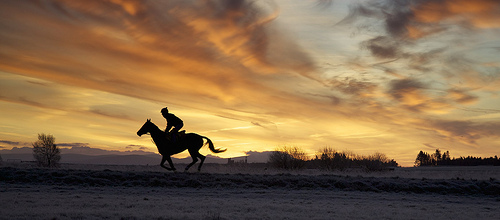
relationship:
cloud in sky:
[0, 0, 500, 166] [1, 1, 498, 171]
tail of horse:
[201, 135, 228, 155] [135, 118, 227, 174]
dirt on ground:
[0, 166, 500, 220] [0, 162, 500, 218]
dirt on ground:
[0, 162, 500, 182] [0, 162, 500, 218]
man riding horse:
[161, 107, 185, 135] [129, 122, 222, 177]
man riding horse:
[161, 107, 185, 135] [138, 122, 222, 173]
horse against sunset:
[138, 122, 222, 173] [3, 2, 498, 161]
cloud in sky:
[0, 0, 500, 166] [12, 4, 466, 113]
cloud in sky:
[376, 2, 492, 53] [12, 4, 466, 113]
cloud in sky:
[0, 0, 500, 166] [424, 28, 444, 50]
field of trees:
[35, 154, 259, 218] [412, 145, 499, 170]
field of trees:
[0, 154, 500, 220] [259, 145, 402, 174]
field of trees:
[0, 154, 500, 220] [412, 146, 497, 168]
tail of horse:
[200, 136, 227, 153] [133, 118, 225, 170]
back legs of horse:
[191, 148, 214, 177] [138, 119, 221, 169]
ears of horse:
[141, 113, 156, 125] [132, 115, 219, 175]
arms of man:
[159, 118, 173, 131] [161, 107, 185, 135]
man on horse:
[161, 107, 185, 135] [134, 110, 211, 177]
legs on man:
[159, 122, 189, 138] [161, 107, 185, 135]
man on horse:
[161, 107, 185, 135] [133, 118, 225, 170]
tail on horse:
[200, 136, 227, 153] [133, 118, 225, 170]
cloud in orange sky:
[0, 0, 500, 166] [0, 0, 500, 168]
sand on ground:
[3, 185, 498, 218] [21, 185, 227, 218]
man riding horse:
[158, 107, 180, 129] [138, 120, 216, 172]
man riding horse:
[161, 107, 185, 135] [133, 118, 225, 170]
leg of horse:
[158, 156, 171, 172] [135, 118, 227, 174]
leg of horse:
[167, 157, 179, 173] [135, 118, 227, 174]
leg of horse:
[185, 148, 200, 172] [135, 118, 227, 174]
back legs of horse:
[192, 148, 207, 172] [135, 118, 227, 174]